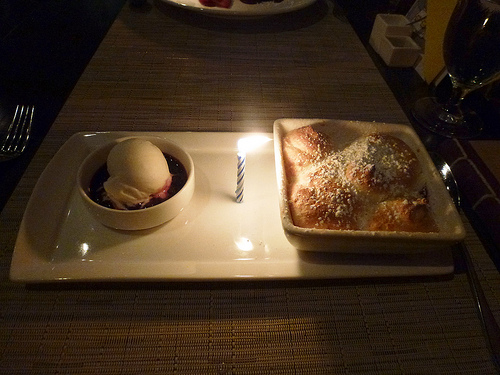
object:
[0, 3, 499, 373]
table runner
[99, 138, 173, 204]
ice cream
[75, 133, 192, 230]
bowl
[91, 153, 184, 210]
sauce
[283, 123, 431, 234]
pastry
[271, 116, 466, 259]
dish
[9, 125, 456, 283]
serving tray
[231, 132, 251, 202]
candle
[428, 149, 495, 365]
spoon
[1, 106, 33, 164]
fork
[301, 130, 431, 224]
powedered sugar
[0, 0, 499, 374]
table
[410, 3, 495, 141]
glass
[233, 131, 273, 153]
flame